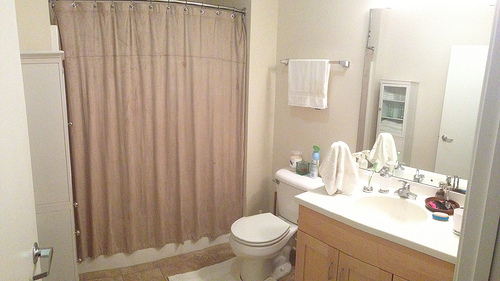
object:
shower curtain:
[49, 0, 251, 262]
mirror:
[359, 6, 490, 194]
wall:
[275, 1, 365, 170]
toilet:
[227, 168, 325, 281]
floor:
[79, 241, 299, 280]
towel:
[285, 58, 330, 109]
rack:
[280, 59, 350, 67]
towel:
[319, 142, 358, 197]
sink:
[351, 196, 427, 229]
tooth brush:
[367, 162, 379, 186]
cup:
[380, 167, 390, 193]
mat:
[78, 242, 234, 281]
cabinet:
[292, 184, 456, 281]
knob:
[442, 135, 453, 143]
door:
[433, 40, 489, 179]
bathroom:
[0, 0, 500, 280]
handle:
[272, 179, 280, 184]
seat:
[230, 212, 290, 247]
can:
[308, 145, 320, 179]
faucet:
[395, 180, 418, 200]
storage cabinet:
[375, 80, 417, 167]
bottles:
[289, 151, 302, 171]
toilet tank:
[273, 168, 324, 225]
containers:
[425, 197, 460, 216]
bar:
[159, 0, 245, 13]